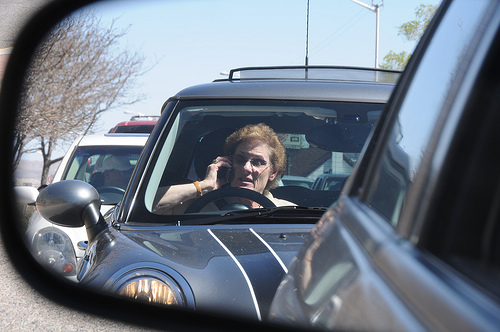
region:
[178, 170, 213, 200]
Person has orange band on wrist.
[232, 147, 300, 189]
Person has glasses on face.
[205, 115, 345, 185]
Person has brown hair.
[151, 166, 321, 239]
Person is driving a car.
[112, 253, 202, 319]
Headlight on car is turned on.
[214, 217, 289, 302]
Black stripe on hood of car.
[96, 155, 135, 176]
Person is wearing white hat.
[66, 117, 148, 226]
White car behind gray car.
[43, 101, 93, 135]
Branches on tree are bare.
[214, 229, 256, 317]
White stripe on hood of car.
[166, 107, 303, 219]
A woman talking on a cell phone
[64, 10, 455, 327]
A reflection in a car side mirror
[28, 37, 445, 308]
A woman in a gray mini cooper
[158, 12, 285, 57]
A blue sky in the background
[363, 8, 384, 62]
A gray metal light pole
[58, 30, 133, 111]
Tree branches with no leaves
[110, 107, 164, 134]
The roof of a red vehicle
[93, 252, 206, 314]
The lit headlight of a mini cooper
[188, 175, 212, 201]
A woman's orange bracelet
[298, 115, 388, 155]
A rear view mirror of a mini cooper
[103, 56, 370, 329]
the mirror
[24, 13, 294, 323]
the mirror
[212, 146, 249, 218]
Person holding phone in hand.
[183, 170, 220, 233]
Orange band around person's wrist.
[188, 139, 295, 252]
Person is driving a car.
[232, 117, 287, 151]
Person has brown hair.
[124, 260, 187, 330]
Headlights on car are turned on.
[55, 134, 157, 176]
White car behind gray car.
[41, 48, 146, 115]
Tree branches are bare.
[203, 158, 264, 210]
Person is holding cellphone in hand.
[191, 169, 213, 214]
Band around person's wrist.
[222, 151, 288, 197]
Glasses on person's face.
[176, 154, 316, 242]
Person driving a car.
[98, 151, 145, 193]
Person wearing white hat.